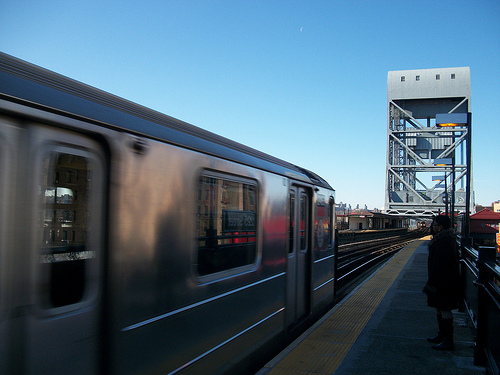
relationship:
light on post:
[435, 113, 468, 128] [465, 112, 472, 212]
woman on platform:
[423, 215, 462, 350] [250, 234, 472, 374]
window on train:
[197, 171, 257, 284] [1, 52, 338, 374]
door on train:
[3, 112, 109, 375] [1, 52, 338, 374]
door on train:
[287, 180, 310, 330] [1, 52, 338, 374]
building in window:
[198, 179, 224, 246] [197, 171, 257, 284]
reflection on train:
[258, 217, 289, 265] [1, 52, 338, 374]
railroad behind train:
[334, 228, 429, 302] [1, 52, 338, 374]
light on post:
[434, 155, 454, 170] [452, 159, 455, 223]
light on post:
[431, 174, 443, 182] [444, 177, 449, 216]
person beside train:
[423, 215, 462, 350] [1, 52, 338, 374]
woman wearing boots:
[423, 215, 462, 350] [427, 315, 454, 352]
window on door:
[38, 151, 91, 312] [3, 112, 109, 375]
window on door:
[289, 192, 294, 256] [3, 112, 109, 375]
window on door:
[300, 195, 307, 251] [287, 180, 310, 330]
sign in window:
[221, 210, 257, 232] [197, 171, 257, 284]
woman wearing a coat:
[423, 215, 462, 350] [425, 235, 460, 309]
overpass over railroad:
[385, 208, 440, 217] [334, 228, 429, 302]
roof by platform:
[468, 219, 495, 230] [250, 234, 472, 374]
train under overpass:
[416, 219, 426, 230] [385, 208, 440, 217]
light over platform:
[435, 113, 468, 128] [250, 234, 472, 374]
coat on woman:
[425, 235, 460, 309] [423, 215, 462, 350]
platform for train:
[250, 234, 472, 374] [1, 52, 338, 374]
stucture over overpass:
[388, 69, 474, 218] [385, 208, 440, 217]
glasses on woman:
[430, 223, 442, 228] [423, 215, 462, 350]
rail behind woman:
[455, 237, 499, 374] [423, 215, 462, 350]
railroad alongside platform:
[334, 228, 429, 302] [250, 234, 472, 374]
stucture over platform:
[388, 69, 474, 218] [250, 234, 472, 374]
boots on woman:
[427, 315, 454, 352] [423, 215, 462, 350]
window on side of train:
[289, 192, 294, 256] [1, 52, 338, 374]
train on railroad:
[1, 52, 338, 374] [334, 228, 429, 302]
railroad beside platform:
[334, 228, 429, 302] [250, 234, 472, 374]